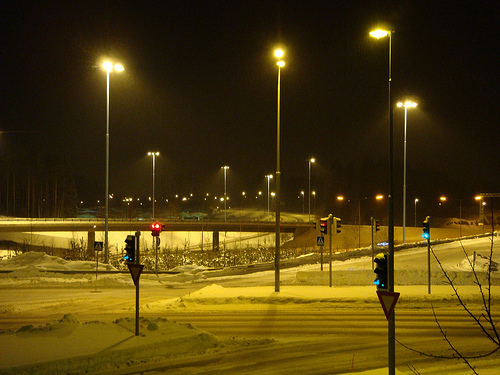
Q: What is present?
A: Snow.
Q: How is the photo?
A: Clear.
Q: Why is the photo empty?
A: There is no one.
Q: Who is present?
A: Nobody.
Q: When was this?
A: Nighttime.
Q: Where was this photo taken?
A: Freeway.